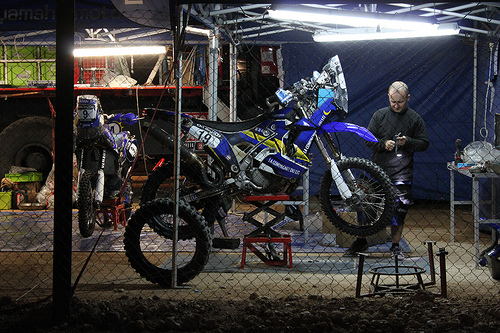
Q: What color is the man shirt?
A: Jet black.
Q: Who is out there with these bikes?
A: A man.